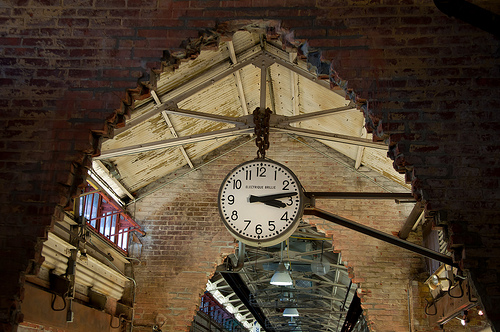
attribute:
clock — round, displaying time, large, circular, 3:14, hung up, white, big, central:
[218, 157, 315, 249]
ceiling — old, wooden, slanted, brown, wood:
[87, 21, 412, 209]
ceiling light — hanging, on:
[270, 241, 293, 286]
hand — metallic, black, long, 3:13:
[250, 192, 298, 203]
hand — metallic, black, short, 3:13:
[250, 195, 287, 208]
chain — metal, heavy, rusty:
[252, 106, 272, 158]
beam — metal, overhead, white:
[92, 49, 389, 161]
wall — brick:
[0, 0, 499, 332]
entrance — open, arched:
[16, 26, 492, 332]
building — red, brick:
[0, 0, 499, 332]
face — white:
[220, 161, 299, 240]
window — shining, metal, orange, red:
[116, 214, 130, 253]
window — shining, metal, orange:
[98, 197, 118, 244]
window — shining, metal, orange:
[78, 184, 99, 229]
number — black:
[256, 166, 266, 177]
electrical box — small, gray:
[66, 310, 74, 322]